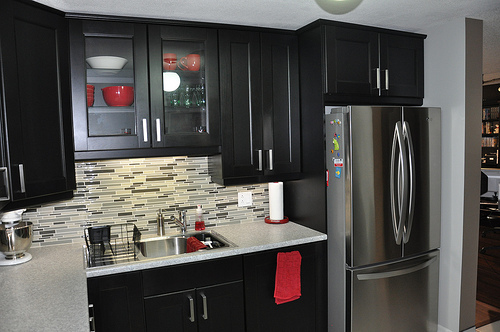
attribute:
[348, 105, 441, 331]
refrigerator — large, stainless steel, silver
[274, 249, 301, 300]
towel — red, hanging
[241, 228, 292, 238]
countertop — gray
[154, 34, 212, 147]
cabinet — black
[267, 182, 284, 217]
paper towels — rolled, white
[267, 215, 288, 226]
holder — red, brown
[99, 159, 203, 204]
wall — brick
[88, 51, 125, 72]
bowl — white, large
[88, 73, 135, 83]
shelf — glass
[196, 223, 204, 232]
soap — red, liquid, orange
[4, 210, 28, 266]
mixer — white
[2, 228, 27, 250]
bowl — stainless steel, silver, aluminum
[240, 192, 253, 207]
light switch — white, electrical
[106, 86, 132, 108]
bowl — red, large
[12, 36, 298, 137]
cabinets — dark brown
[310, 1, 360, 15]
fixture — white, round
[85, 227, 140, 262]
drainer — silver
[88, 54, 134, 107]
dishes — red, white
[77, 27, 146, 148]
door — glass